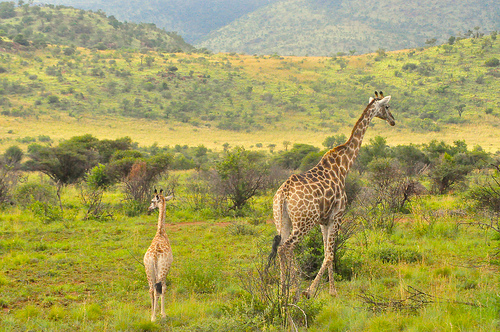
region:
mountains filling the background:
[125, 13, 367, 75]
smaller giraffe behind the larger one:
[140, 184, 195, 316]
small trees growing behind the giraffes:
[25, 138, 264, 212]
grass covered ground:
[24, 242, 114, 309]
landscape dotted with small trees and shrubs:
[65, 64, 347, 113]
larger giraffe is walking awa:
[263, 77, 401, 297]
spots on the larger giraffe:
[304, 170, 334, 216]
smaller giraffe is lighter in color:
[140, 186, 175, 316]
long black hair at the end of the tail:
[265, 232, 283, 269]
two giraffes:
[133, 79, 405, 321]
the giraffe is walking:
[250, 43, 430, 290]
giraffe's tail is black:
[258, 229, 295, 283]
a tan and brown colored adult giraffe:
[272, 90, 398, 297]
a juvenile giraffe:
[138, 186, 176, 320]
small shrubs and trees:
[3, 133, 495, 224]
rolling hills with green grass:
[3, 1, 498, 128]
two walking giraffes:
[142, 90, 394, 320]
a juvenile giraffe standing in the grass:
[140, 185, 172, 322]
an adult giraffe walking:
[265, 88, 397, 319]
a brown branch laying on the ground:
[350, 282, 482, 314]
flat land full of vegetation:
[1, 135, 498, 327]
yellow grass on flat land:
[2, 120, 497, 150]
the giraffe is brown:
[232, 72, 402, 327]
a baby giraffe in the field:
[106, 151, 202, 316]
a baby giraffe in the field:
[124, 172, 182, 307]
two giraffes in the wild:
[79, 40, 469, 330]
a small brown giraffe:
[110, 160, 210, 323]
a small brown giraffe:
[130, 175, 184, 313]